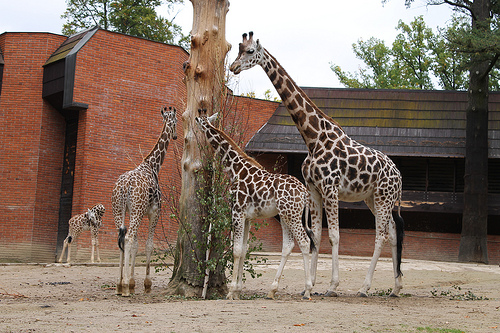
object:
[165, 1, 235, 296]
tree trunk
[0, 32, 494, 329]
enclosure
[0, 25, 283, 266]
building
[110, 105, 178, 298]
giraffe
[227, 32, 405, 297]
giraffe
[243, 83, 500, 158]
roof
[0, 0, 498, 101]
sky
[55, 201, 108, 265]
giraffe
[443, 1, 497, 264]
tree trunk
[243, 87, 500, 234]
building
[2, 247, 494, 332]
ground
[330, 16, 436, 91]
trees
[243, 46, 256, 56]
left eye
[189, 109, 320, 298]
giraffes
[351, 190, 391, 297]
left rear leg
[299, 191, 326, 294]
right front leg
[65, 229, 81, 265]
rear legs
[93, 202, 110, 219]
neck